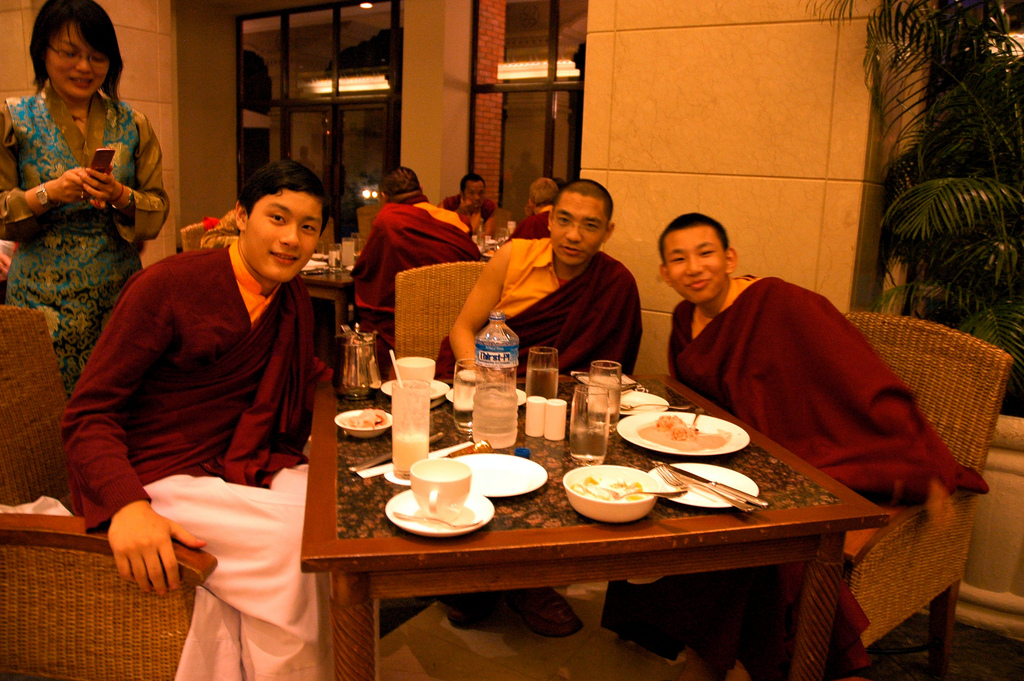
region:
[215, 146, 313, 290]
the head of a man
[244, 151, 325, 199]
the hair of a man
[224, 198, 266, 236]
the ear of a man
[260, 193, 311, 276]
the face of a man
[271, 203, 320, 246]
the eyes of a man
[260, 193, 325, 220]
the eyebrow of a man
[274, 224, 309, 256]
the nose of a man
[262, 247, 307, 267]
the mouth of a man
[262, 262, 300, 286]
the chin of a man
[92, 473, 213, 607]
the hand of a man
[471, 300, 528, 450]
bottle of water on the table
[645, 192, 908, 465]
guy wearing a red toga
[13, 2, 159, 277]
woman is wearing a blue dress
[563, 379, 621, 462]
clear glass on the table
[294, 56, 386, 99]
reflection of a light in the window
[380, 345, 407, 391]
straw in the cup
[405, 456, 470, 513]
coffee mug on the plate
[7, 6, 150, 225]
woman looking at her cellphone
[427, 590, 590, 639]
pair of shoes under the table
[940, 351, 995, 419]
back of the wicker chair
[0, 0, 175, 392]
woman holding pink phone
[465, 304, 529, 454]
large bottle of drinking water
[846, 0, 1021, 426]
scene of large greenery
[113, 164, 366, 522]
Man with dark hair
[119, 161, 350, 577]
Monk with dark hair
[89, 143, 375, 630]
Man wearing red robe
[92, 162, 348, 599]
Monk wearing red robe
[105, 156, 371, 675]
Man sitting at table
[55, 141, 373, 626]
Monk sitting at table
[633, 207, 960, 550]
Monk sitting at table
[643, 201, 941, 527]
Man with short hair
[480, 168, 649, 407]
Monk with short hair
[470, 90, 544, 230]
glass is clean and clear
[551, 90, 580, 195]
glass is clean and clear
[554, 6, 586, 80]
glass is clean and clear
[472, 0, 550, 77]
glass is clean and clear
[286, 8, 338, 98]
glass is clean and clearglass is clean and clear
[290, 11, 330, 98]
glass is clean and clear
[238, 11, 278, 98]
glass is clean and clear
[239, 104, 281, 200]
glass is clean and clear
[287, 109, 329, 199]
glass is clean and clear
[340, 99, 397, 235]
glass is clean and clear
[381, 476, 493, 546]
white dish on the wooden table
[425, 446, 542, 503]
white dish on the wooden table